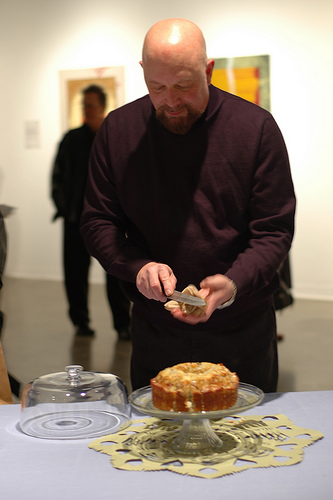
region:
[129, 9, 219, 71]
Man's head is bald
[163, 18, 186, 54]
Man's head has shiny spot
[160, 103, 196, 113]
Man has a mustache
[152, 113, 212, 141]
Man has a beard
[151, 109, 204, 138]
Man's beard is trimmed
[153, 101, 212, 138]
Man's facial hair is brown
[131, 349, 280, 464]
Cake on a crystal cake server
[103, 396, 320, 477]
Cake server on a white doily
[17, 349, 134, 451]
Lid to cake server on table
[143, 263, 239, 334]
Man cutting piece of cake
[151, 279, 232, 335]
man has knife in his hand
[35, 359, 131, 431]
glass top of cake dish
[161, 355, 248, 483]
cake on cake plate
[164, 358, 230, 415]
cake has been sliced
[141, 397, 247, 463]
cake plater is clear glass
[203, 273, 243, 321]
man is wearing a watch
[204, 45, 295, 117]
painting on the wall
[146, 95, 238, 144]
man has a goatee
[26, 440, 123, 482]
table cloth is baby blue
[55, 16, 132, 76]
light reflection on wall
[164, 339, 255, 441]
A cake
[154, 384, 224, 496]
A cake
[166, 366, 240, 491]
A cake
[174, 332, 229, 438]
A cake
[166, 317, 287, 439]
A cake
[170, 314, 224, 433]
A cake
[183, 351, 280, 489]
A cake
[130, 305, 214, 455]
A cake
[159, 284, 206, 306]
a large knife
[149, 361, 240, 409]
a cake with icing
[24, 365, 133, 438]
a glass cake dish lid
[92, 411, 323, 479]
a large placemat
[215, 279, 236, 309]
a gray male's wristwatch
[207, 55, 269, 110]
a green picture frame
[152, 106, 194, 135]
the beard of a man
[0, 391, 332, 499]
a purple tablecloth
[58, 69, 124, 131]
a white picture frame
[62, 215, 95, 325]
the leg of a man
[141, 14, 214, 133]
The man is bald.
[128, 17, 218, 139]
The man has a moustache.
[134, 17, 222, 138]
The man has a beard.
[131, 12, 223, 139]
The man's head is cleanshaven.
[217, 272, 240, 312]
The man is wearing a watch.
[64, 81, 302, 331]
The man is wearing a shirt.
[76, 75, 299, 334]
The shirt is brown.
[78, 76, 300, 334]
The shirt has long sleeves.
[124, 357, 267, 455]
The cake is on a cake plate.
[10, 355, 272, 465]
The lid is next to the cake pedestal.